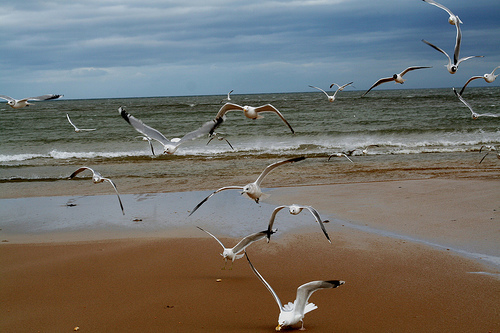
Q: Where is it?
A: This is at the beach.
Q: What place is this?
A: It is a beach.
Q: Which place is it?
A: It is a beach.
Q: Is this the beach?
A: Yes, it is the beach.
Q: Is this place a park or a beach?
A: It is a beach.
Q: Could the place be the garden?
A: No, it is the beach.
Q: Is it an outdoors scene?
A: Yes, it is outdoors.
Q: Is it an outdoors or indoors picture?
A: It is outdoors.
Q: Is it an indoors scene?
A: No, it is outdoors.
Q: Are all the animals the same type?
A: Yes, all the animals are birds.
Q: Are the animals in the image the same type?
A: Yes, all the animals are birds.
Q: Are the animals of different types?
A: No, all the animals are birds.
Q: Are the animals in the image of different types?
A: No, all the animals are birds.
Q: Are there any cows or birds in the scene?
A: Yes, there is a bird.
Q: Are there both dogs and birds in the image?
A: No, there is a bird but no dogs.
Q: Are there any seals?
A: No, there are no seals.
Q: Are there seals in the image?
A: No, there are no seals.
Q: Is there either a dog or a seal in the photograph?
A: No, there are no seals or dogs.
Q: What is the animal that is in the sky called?
A: The animal is a bird.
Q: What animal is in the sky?
A: The animal is a bird.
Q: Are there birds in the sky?
A: Yes, there is a bird in the sky.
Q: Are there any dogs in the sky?
A: No, there is a bird in the sky.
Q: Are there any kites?
A: No, there are no kites.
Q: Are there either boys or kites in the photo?
A: No, there are no kites or boys.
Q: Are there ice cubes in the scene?
A: No, there are no ice cubes.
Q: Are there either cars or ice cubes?
A: No, there are no ice cubes or cars.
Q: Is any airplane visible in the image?
A: No, there are no airplanes.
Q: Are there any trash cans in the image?
A: No, there are no trash cans.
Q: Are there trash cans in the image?
A: No, there are no trash cans.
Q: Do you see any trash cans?
A: No, there are no trash cans.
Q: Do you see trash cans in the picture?
A: No, there are no trash cans.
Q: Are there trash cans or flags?
A: No, there are no trash cans or flags.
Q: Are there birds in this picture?
A: Yes, there is a bird.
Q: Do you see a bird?
A: Yes, there is a bird.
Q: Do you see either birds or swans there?
A: Yes, there is a bird.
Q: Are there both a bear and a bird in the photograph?
A: No, there is a bird but no bears.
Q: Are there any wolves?
A: No, there are no wolves.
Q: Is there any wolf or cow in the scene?
A: No, there are no wolves or cows.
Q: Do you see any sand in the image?
A: Yes, there is sand.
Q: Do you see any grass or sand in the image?
A: Yes, there is sand.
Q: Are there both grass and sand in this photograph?
A: No, there is sand but no grass.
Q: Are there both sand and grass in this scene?
A: No, there is sand but no grass.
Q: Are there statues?
A: No, there are no statues.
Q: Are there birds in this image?
A: Yes, there is a bird.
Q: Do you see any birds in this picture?
A: Yes, there is a bird.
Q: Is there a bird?
A: Yes, there is a bird.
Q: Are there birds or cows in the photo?
A: Yes, there is a bird.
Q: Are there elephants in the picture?
A: No, there are no elephants.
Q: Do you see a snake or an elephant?
A: No, there are no elephants or snakes.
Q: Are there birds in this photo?
A: Yes, there is a bird.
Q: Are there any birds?
A: Yes, there is a bird.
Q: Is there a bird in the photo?
A: Yes, there is a bird.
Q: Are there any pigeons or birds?
A: Yes, there is a bird.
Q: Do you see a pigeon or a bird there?
A: Yes, there is a bird.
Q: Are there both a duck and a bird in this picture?
A: No, there is a bird but no ducks.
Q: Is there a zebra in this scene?
A: No, there are no zebras.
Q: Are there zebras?
A: No, there are no zebras.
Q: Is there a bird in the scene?
A: Yes, there is a bird.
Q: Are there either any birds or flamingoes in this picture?
A: Yes, there is a bird.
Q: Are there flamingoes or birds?
A: Yes, there is a bird.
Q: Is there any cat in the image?
A: No, there are no cats.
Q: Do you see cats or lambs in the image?
A: No, there are no cats or lambs.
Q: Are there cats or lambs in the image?
A: No, there are no cats or lambs.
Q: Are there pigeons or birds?
A: Yes, there is a bird.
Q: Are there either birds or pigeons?
A: Yes, there is a bird.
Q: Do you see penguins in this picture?
A: No, there are no penguins.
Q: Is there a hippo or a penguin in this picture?
A: No, there are no penguins or hippos.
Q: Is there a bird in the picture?
A: Yes, there is a bird.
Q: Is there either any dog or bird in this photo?
A: Yes, there is a bird.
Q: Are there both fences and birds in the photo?
A: No, there is a bird but no fences.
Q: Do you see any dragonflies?
A: No, there are no dragonflies.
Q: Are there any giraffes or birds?
A: Yes, there is a bird.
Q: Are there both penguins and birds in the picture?
A: No, there is a bird but no penguins.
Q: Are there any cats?
A: No, there are no cats.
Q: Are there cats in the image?
A: No, there are no cats.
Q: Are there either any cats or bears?
A: No, there are no cats or bears.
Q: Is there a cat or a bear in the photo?
A: No, there are no cats or bears.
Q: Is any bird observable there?
A: Yes, there is a bird.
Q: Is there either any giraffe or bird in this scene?
A: Yes, there is a bird.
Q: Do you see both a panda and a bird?
A: No, there is a bird but no pandas.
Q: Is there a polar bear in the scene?
A: No, there are no polar bears.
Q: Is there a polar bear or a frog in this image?
A: No, there are no polar bears or frogs.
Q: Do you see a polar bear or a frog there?
A: No, there are no polar bears or frogs.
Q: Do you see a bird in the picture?
A: Yes, there is a bird.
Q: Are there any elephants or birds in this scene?
A: Yes, there is a bird.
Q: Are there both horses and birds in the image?
A: No, there is a bird but no horses.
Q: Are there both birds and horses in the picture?
A: No, there is a bird but no horses.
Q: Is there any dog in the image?
A: No, there are no dogs.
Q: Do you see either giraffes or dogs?
A: No, there are no dogs or giraffes.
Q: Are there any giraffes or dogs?
A: No, there are no dogs or giraffes.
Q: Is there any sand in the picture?
A: Yes, there is sand.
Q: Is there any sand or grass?
A: Yes, there is sand.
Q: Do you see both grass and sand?
A: No, there is sand but no grass.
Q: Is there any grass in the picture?
A: No, there is no grass.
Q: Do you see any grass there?
A: No, there is no grass.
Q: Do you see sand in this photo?
A: Yes, there is sand.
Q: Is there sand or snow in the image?
A: Yes, there is sand.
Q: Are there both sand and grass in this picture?
A: No, there is sand but no grass.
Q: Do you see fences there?
A: No, there are no fences.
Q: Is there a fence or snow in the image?
A: No, there are no fences or snow.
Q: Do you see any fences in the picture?
A: No, there are no fences.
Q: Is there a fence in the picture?
A: No, there are no fences.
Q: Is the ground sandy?
A: Yes, the ground is sandy.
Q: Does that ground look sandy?
A: Yes, the ground is sandy.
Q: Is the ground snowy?
A: No, the ground is sandy.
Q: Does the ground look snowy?
A: No, the ground is sandy.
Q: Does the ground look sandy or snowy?
A: The ground is sandy.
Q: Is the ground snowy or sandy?
A: The ground is sandy.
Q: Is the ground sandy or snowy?
A: The ground is sandy.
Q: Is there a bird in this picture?
A: Yes, there is a bird.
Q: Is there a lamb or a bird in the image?
A: Yes, there is a bird.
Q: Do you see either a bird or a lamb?
A: Yes, there is a bird.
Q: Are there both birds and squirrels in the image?
A: No, there is a bird but no squirrels.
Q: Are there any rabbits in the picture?
A: No, there are no rabbits.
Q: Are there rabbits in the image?
A: No, there are no rabbits.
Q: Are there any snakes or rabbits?
A: No, there are no rabbits or snakes.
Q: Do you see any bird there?
A: Yes, there is a bird.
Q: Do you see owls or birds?
A: Yes, there is a bird.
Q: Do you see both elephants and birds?
A: No, there is a bird but no elephants.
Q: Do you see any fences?
A: No, there are no fences.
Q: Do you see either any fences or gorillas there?
A: No, there are no fences or gorillas.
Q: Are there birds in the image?
A: Yes, there is a bird.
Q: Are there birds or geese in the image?
A: Yes, there is a bird.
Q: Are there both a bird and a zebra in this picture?
A: No, there is a bird but no zebras.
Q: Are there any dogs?
A: No, there are no dogs.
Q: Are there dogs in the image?
A: No, there are no dogs.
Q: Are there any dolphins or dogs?
A: No, there are no dogs or dolphins.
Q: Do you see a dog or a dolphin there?
A: No, there are no dogs or dolphins.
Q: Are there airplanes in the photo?
A: No, there are no airplanes.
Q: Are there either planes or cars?
A: No, there are no planes or cars.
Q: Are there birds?
A: Yes, there are birds.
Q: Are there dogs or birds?
A: Yes, there are birds.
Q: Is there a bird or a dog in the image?
A: Yes, there are birds.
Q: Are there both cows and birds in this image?
A: No, there are birds but no cows.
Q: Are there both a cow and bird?
A: No, there are birds but no cows.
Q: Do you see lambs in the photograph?
A: No, there are no lambs.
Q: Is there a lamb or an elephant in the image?
A: No, there are no lambs or elephants.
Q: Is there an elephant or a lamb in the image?
A: No, there are no lambs or elephants.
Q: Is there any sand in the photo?
A: Yes, there is sand.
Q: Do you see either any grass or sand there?
A: Yes, there is sand.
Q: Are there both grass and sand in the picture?
A: No, there is sand but no grass.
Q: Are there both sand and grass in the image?
A: No, there is sand but no grass.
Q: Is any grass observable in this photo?
A: No, there is no grass.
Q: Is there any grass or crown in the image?
A: No, there are no grass or crowns.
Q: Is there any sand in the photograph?
A: Yes, there is sand.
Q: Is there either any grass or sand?
A: Yes, there is sand.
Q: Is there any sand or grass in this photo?
A: Yes, there is sand.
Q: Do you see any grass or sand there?
A: Yes, there is sand.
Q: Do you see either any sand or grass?
A: Yes, there is sand.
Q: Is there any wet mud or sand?
A: Yes, there is wet sand.